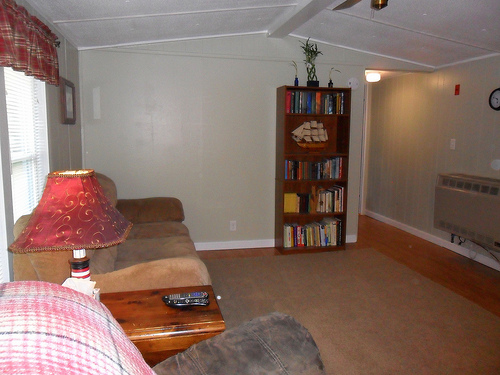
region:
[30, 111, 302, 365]
the table is wooden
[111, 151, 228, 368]
the table is wooden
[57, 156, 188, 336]
the table is wooden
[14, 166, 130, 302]
lamp on top of a side table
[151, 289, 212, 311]
two television remote controls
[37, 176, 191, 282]
brown fuzzy sofa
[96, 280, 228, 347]
brown wooden side table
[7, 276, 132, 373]
red and white blanket on top of chair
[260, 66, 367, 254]
brown book shelf in the room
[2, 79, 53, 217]
white blinds on the windows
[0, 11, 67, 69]
red and white material hanging from top of windows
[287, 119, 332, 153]
small replica of an old ship on book shelf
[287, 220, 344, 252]
collection of books on shelf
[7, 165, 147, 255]
Pink lampshade in the room.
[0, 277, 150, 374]
Afghan thrown over chair.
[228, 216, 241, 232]
Outlet on the wall.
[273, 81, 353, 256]
Bookshelf against the wall.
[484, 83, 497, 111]
Clock on the wall.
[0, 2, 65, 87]
Plaid valance over the windows.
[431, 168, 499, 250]
Wall heater on the wall.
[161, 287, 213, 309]
Remote controls on the table.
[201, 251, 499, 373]
Area rug on the floor.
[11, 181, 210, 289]
Tan couch against the wall.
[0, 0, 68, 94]
red plaid window valance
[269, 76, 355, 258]
tall bookshelf against wall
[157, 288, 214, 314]
remote controls on wood table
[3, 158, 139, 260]
red lamp shade with gold swirls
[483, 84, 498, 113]
black and white wall clock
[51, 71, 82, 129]
brown frame picture on wall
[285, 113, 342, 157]
decorative ship on shelf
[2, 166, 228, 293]
beige living room sofa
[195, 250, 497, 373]
brown area rug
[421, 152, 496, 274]
heat and cooling unit